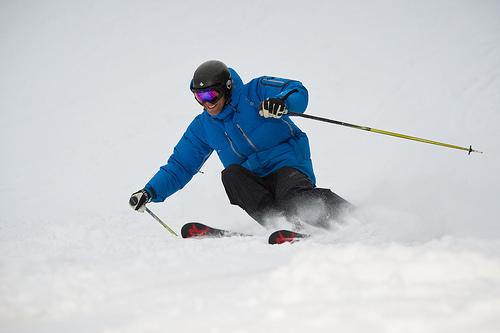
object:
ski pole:
[256, 98, 486, 156]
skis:
[178, 222, 237, 241]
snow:
[293, 184, 496, 252]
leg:
[220, 163, 306, 232]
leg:
[270, 166, 356, 238]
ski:
[267, 229, 315, 246]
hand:
[257, 96, 288, 119]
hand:
[122, 187, 156, 214]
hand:
[128, 190, 152, 212]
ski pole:
[143, 204, 178, 237]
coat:
[142, 66, 317, 203]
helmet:
[188, 59, 233, 116]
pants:
[219, 164, 374, 231]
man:
[126, 59, 371, 229]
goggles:
[188, 83, 224, 105]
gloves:
[127, 188, 152, 213]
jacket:
[143, 68, 316, 203]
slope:
[4, 6, 500, 310]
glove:
[256, 95, 289, 120]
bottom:
[180, 222, 254, 243]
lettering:
[275, 81, 306, 105]